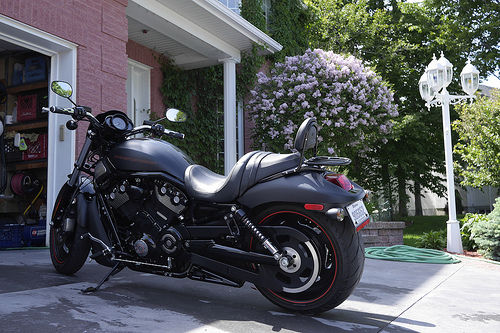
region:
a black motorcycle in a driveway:
[40, 79, 367, 313]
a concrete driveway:
[1, 252, 498, 332]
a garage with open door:
[0, 40, 48, 250]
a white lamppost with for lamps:
[420, 52, 477, 253]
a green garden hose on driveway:
[366, 245, 457, 265]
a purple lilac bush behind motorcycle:
[248, 49, 400, 161]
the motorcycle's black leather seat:
[185, 118, 316, 199]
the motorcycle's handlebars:
[44, 81, 184, 138]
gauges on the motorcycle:
[106, 113, 130, 132]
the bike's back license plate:
[346, 200, 368, 227]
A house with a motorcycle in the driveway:
[0, 0, 499, 331]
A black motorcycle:
[41, 80, 371, 317]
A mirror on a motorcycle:
[52, 79, 72, 98]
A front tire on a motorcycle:
[49, 181, 91, 276]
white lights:
[419, 52, 481, 254]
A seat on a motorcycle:
[184, 150, 259, 206]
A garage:
[0, 38, 47, 249]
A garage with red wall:
[1, 1, 126, 249]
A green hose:
[364, 243, 461, 264]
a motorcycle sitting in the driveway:
[34, 78, 376, 312]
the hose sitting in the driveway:
[367, 238, 459, 264]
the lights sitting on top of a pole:
[411, 46, 486, 247]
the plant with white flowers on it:
[251, 49, 402, 156]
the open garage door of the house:
[0, 46, 47, 243]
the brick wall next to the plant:
[363, 219, 409, 247]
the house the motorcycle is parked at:
[4, 0, 266, 235]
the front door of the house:
[129, 61, 158, 136]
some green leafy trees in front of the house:
[258, 4, 495, 194]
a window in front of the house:
[201, 88, 240, 165]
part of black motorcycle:
[244, 185, 374, 316]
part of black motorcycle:
[223, 195, 286, 275]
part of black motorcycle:
[233, 160, 363, 221]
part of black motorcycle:
[187, 103, 323, 205]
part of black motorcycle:
[113, 132, 199, 183]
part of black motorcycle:
[31, 74, 194, 144]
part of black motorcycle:
[67, 125, 99, 184]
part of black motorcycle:
[39, 173, 100, 279]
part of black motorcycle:
[155, 222, 180, 257]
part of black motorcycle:
[126, 231, 154, 263]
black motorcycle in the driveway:
[47, 78, 363, 325]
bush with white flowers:
[257, 40, 395, 185]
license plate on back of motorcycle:
[347, 199, 367, 224]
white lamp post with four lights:
[417, 52, 491, 254]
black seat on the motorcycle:
[180, 146, 297, 199]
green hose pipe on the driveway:
[365, 237, 453, 269]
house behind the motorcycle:
[0, 4, 291, 279]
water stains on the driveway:
[4, 237, 494, 332]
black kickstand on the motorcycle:
[82, 268, 127, 298]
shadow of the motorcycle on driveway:
[94, 280, 416, 330]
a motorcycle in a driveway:
[40, 82, 370, 318]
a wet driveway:
[1, 221, 498, 332]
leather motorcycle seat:
[188, 150, 255, 202]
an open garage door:
[0, 38, 58, 250]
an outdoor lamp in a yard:
[414, 52, 479, 263]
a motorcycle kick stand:
[82, 265, 118, 295]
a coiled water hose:
[364, 244, 459, 264]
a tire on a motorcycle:
[251, 207, 364, 314]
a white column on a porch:
[219, 56, 238, 176]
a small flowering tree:
[245, 49, 400, 170]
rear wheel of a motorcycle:
[236, 195, 374, 328]